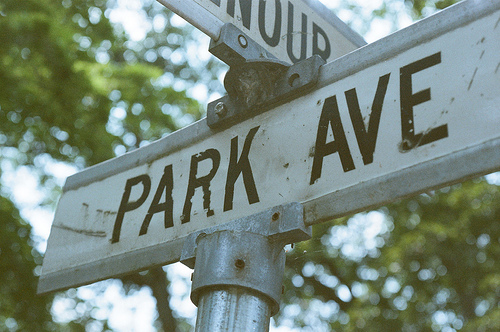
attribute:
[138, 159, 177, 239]
letter — black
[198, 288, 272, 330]
pole — gray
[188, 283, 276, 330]
metal pole — silver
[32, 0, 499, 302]
sign — white, black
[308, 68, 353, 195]
letter — black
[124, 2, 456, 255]
sign — dirty 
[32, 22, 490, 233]
sign — white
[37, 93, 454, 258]
signs — street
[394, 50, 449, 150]
letter — black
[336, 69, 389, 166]
v — black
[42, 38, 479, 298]
signboard — white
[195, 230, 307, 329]
pole — silver, metal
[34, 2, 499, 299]
street sign — gray, white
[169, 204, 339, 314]
pole — metal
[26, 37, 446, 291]
sign — white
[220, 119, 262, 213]
letter — black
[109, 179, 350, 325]
pole — silver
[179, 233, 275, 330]
pole — metal